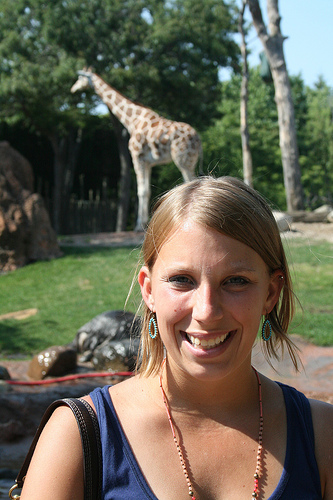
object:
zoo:
[0, 0, 332, 498]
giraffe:
[70, 67, 199, 236]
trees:
[240, 3, 252, 194]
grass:
[0, 233, 332, 361]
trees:
[0, 0, 70, 140]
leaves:
[5, 5, 17, 24]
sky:
[216, 1, 333, 80]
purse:
[8, 390, 124, 496]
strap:
[6, 393, 105, 498]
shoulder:
[58, 374, 136, 443]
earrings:
[147, 312, 158, 341]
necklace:
[158, 355, 264, 500]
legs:
[132, 154, 148, 232]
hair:
[127, 171, 304, 377]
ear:
[137, 264, 155, 314]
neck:
[162, 347, 254, 408]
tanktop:
[88, 381, 324, 498]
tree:
[201, 52, 333, 209]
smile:
[180, 325, 238, 359]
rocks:
[76, 309, 140, 376]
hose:
[6, 360, 136, 388]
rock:
[28, 344, 80, 382]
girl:
[18, 174, 333, 498]